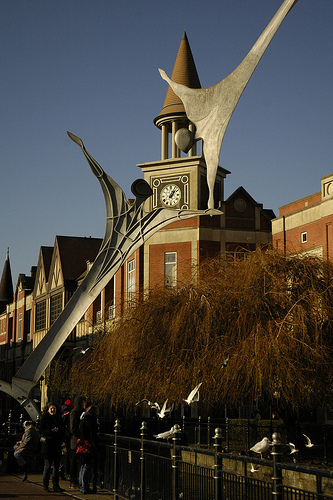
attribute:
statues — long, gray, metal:
[112, 177, 174, 286]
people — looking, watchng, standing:
[37, 427, 182, 480]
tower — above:
[147, 45, 205, 161]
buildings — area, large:
[23, 238, 280, 377]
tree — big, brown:
[229, 293, 291, 331]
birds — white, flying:
[125, 375, 170, 413]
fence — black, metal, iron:
[225, 442, 291, 487]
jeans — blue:
[67, 472, 111, 495]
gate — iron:
[79, 434, 136, 463]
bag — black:
[68, 440, 95, 450]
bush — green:
[68, 360, 122, 389]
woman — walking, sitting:
[62, 396, 116, 488]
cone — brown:
[186, 31, 224, 124]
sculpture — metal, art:
[67, 129, 143, 215]